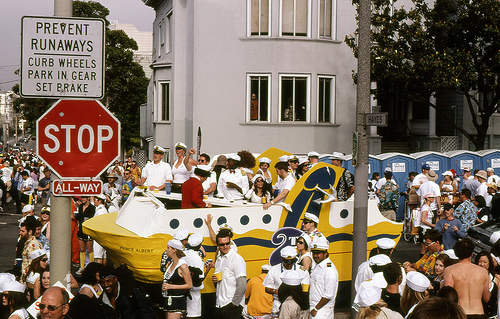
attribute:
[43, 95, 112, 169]
sign — white, red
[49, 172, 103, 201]
sign — red, white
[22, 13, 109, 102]
sign — black, white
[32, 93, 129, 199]
stop sign — red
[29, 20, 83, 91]
word — black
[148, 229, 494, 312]
people — standing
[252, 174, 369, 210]
people — dressed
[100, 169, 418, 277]
float — yellow, blue, white, boat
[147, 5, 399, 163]
building — gray, white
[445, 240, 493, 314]
man — topless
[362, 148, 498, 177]
outhouses — blue, lined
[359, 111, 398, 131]
signage — white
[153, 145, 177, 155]
hat — white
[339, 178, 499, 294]
crowd — large, people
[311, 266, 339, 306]
shirt — white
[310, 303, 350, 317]
pants — white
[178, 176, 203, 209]
shirt — red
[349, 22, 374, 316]
pole — tall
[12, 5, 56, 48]
sky — grey